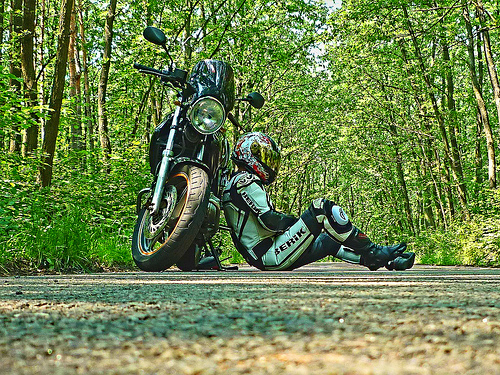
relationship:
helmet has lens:
[234, 128, 280, 180] [248, 140, 283, 173]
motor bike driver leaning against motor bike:
[225, 131, 416, 270] [127, 26, 267, 269]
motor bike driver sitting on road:
[225, 131, 416, 270] [3, 257, 498, 374]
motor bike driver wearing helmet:
[225, 131, 416, 270] [234, 128, 280, 180]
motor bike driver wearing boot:
[225, 131, 416, 270] [359, 238, 405, 269]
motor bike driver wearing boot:
[225, 131, 416, 270] [388, 249, 417, 269]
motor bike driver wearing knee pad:
[225, 131, 416, 270] [327, 200, 353, 237]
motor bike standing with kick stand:
[127, 26, 267, 269] [205, 233, 237, 274]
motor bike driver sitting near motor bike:
[225, 131, 416, 270] [127, 26, 267, 269]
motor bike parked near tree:
[127, 26, 267, 269] [41, 3, 72, 192]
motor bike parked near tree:
[127, 26, 267, 269] [99, 3, 120, 178]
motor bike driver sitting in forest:
[225, 131, 416, 270] [3, 1, 499, 270]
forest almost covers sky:
[3, 1, 499, 270] [3, 2, 484, 180]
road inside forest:
[3, 257, 498, 374] [3, 1, 499, 270]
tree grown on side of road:
[41, 3, 72, 192] [3, 257, 498, 374]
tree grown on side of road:
[99, 3, 120, 178] [3, 257, 498, 374]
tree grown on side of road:
[271, 81, 315, 214] [3, 257, 498, 374]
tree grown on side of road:
[357, 6, 422, 234] [3, 257, 498, 374]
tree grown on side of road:
[396, 3, 469, 220] [3, 257, 498, 374]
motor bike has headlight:
[127, 26, 267, 269] [191, 94, 229, 136]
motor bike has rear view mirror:
[127, 26, 267, 269] [141, 21, 185, 73]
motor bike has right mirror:
[127, 26, 267, 269] [233, 90, 266, 109]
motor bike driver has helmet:
[225, 131, 416, 270] [234, 128, 280, 180]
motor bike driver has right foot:
[225, 131, 416, 270] [364, 239, 406, 270]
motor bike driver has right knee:
[225, 131, 416, 270] [309, 198, 343, 232]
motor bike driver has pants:
[225, 131, 416, 270] [258, 195, 374, 277]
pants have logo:
[258, 195, 374, 277] [271, 226, 306, 255]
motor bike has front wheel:
[127, 26, 267, 269] [127, 158, 209, 274]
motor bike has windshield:
[127, 26, 267, 269] [188, 58, 240, 107]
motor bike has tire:
[127, 26, 267, 269] [127, 158, 209, 274]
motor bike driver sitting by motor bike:
[225, 131, 416, 270] [127, 26, 267, 269]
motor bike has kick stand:
[127, 26, 267, 269] [205, 233, 237, 274]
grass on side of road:
[7, 214, 146, 280] [3, 257, 498, 374]